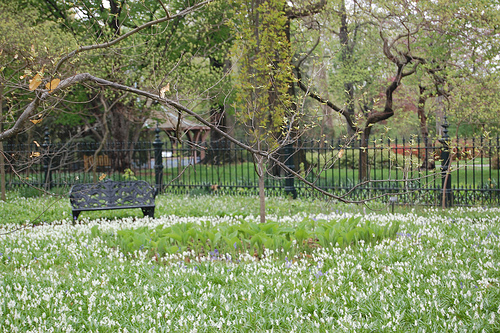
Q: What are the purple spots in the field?
A: Flowers.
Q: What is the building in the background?
A: Gazebo.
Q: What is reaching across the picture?
A: Branch.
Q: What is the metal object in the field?
A: Bench.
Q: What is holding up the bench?
A: Legs.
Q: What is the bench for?
A: Sitting.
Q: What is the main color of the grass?
A: Green.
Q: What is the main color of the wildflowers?
A: White.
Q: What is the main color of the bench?
A: Black.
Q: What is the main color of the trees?
A: Green.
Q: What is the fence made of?
A: Metal.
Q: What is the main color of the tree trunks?
A: Brown.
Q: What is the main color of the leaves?
A: Green.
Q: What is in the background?
A: Trees.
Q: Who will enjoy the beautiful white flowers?
A: Everyone who sees them.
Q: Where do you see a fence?
A: Behind the bench.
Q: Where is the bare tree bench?
A: Over the bench.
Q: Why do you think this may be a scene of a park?
A: Due to the bench, fence and flowers.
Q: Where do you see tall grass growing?
A: By the tree.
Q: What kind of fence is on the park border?
A: Iron fence.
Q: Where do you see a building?
A: In the background behind the bench.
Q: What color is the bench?
A: Black.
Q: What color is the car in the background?
A: Red.